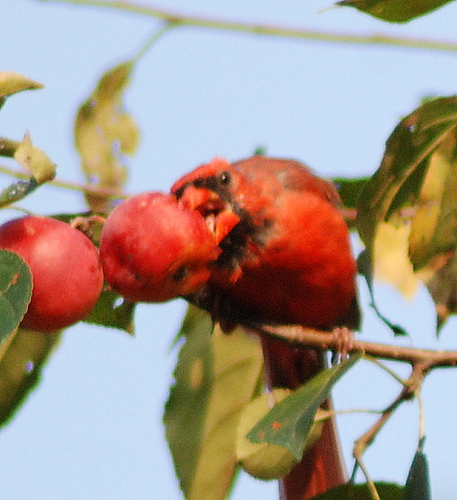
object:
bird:
[170, 153, 357, 347]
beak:
[181, 186, 206, 210]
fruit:
[99, 189, 219, 304]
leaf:
[0, 250, 33, 361]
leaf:
[50, 215, 138, 341]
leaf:
[246, 351, 364, 461]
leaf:
[338, 1, 451, 27]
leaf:
[356, 94, 457, 339]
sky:
[0, 1, 456, 500]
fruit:
[0, 212, 102, 331]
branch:
[185, 294, 456, 499]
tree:
[0, 0, 455, 500]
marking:
[174, 176, 252, 272]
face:
[170, 162, 237, 237]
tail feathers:
[241, 333, 349, 466]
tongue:
[205, 213, 217, 237]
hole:
[113, 296, 122, 307]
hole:
[410, 123, 418, 131]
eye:
[220, 172, 229, 187]